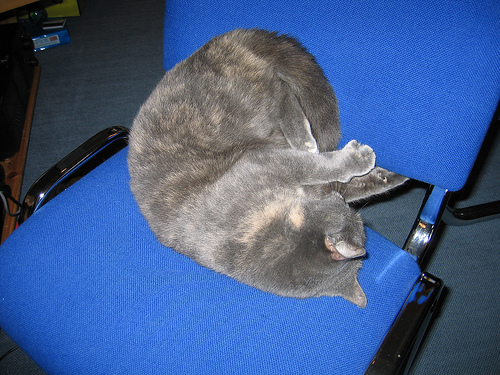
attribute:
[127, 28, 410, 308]
cat — lying, grey, playing, gray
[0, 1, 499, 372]
chair — blue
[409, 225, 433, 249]
reflection — here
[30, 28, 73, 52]
trash — here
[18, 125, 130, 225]
armrest — black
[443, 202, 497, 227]
lever — black